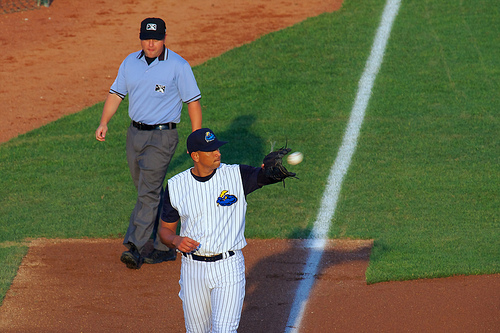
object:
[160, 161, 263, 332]
uniform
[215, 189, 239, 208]
logo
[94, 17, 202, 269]
official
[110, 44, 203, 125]
polo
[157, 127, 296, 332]
player